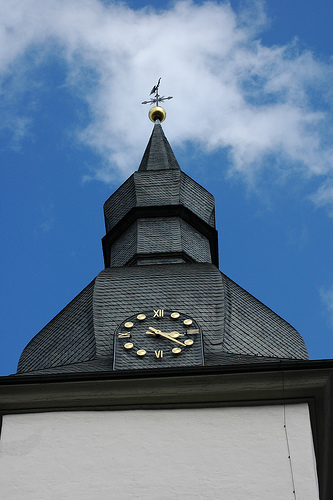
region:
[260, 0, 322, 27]
[art f a cloud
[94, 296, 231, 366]
Clock on the side of a tower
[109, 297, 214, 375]
Clock on the side of a tower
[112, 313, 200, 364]
Clock on the side of a tower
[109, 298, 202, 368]
Clock on the side of a tower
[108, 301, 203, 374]
Clock on the side of a tower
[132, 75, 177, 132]
compass on top of a tower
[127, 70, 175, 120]
compass on top of a tower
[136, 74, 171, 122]
compass on top of a tower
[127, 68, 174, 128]
compass on top of a tower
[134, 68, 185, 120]
compass on top of a tower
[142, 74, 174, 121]
metal figure atop a building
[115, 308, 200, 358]
a simple golden clock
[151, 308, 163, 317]
roman numeral meaning 12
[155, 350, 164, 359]
roman numeral meaning 6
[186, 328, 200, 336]
roman numeral meaning 3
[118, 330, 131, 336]
roman numeral meaning 9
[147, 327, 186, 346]
hands of a clock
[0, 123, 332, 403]
roof of a building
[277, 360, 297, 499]
a thin black wire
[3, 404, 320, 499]
white wall of a building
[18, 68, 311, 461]
tower with clock on it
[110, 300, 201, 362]
clock on face of tower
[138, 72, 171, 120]
post indicating direction on top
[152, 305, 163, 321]
roman numeral on clock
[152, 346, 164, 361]
roman numeral on clock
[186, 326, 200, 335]
roman numeral on clock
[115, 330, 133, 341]
roman numeral on clock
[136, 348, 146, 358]
mark representing number on clock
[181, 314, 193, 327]
mark representing number on clock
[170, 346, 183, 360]
mark representing number on clock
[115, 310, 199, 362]
clock attached to front of building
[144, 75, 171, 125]
weather vane on top of building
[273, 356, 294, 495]
wire hangs from roof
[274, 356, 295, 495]
wire hangs from building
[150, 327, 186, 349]
minute hand tells minute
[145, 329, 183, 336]
hour hand tells hour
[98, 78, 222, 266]
steeple sits atop building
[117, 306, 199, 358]
clock made of golden metal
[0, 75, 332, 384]
rooftop made of black tiles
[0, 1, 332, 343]
partly cloudy blue sky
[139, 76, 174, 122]
golden globe on top of roof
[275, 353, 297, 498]
chord affixed to side of building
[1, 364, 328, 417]
wooden frame is painted black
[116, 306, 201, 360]
time is about 03:22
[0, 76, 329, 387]
clock tower with large dome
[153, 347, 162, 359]
A number on a clock.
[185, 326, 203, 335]
A number on a clock.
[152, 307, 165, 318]
A number on a clock.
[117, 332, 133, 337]
A number on a clock.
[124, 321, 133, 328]
A number on a clock.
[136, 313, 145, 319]
A number on a clock.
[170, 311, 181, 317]
A number on a clock.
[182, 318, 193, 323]
A number on a clock.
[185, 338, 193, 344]
A number on a clock.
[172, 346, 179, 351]
A number on a clock.